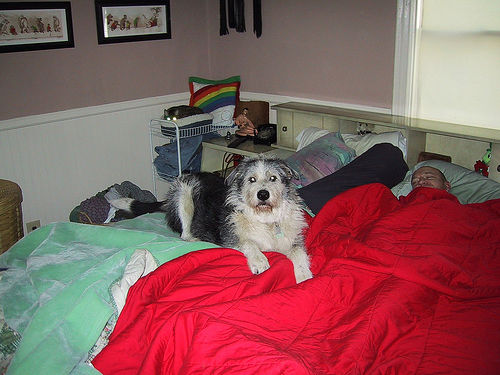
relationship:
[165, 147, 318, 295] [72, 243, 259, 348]
dog on bed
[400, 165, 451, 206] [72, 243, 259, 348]
man on bed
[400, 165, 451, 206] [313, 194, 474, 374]
man under blanket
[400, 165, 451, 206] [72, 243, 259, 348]
man under bed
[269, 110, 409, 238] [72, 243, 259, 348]
pillows on bed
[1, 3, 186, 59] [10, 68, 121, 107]
paintings on wall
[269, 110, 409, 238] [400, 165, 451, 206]
pillows beside man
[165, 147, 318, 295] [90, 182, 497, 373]
dog laying on blanket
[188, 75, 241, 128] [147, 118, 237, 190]
pillow on top of baskets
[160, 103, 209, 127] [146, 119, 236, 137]
cat laying on basket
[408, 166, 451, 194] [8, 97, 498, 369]
head laying in bed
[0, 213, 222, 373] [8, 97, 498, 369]
blanket on bed